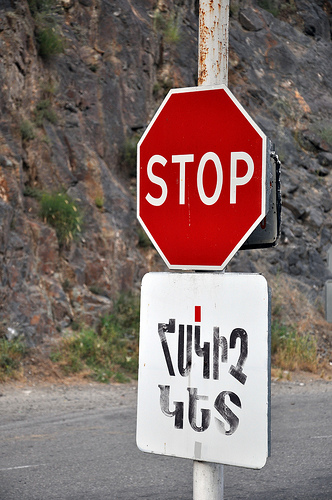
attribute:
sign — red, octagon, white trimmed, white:
[134, 272, 271, 470]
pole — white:
[181, 0, 241, 497]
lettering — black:
[156, 316, 248, 383]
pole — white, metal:
[195, 0, 231, 86]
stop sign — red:
[136, 84, 267, 270]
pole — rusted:
[192, 0, 228, 498]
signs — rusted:
[136, 85, 274, 469]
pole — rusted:
[182, 2, 237, 81]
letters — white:
[145, 144, 253, 211]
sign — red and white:
[111, 94, 306, 318]